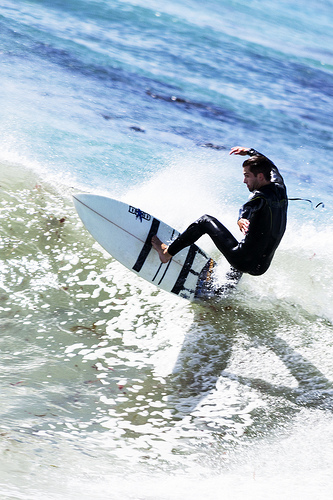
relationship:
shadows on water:
[221, 312, 330, 396] [110, 271, 238, 441]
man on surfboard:
[177, 72, 332, 275] [81, 200, 222, 293]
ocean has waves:
[81, 20, 327, 140] [26, 159, 136, 300]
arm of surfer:
[229, 140, 284, 165] [81, 148, 320, 373]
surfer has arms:
[81, 148, 320, 373] [207, 119, 269, 160]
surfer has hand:
[81, 148, 320, 373] [220, 136, 256, 173]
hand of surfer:
[220, 136, 256, 173] [81, 148, 320, 373]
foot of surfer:
[146, 249, 197, 292] [81, 148, 320, 373]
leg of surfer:
[159, 218, 235, 257] [81, 148, 320, 373]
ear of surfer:
[246, 165, 269, 182] [81, 148, 320, 373]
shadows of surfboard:
[221, 312, 330, 396] [81, 200, 222, 293]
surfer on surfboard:
[81, 148, 320, 373] [81, 200, 222, 293]